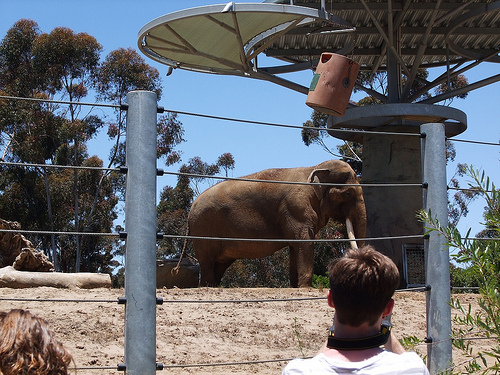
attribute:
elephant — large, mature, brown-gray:
[170, 159, 366, 287]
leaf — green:
[92, 135, 97, 140]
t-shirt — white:
[280, 345, 430, 373]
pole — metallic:
[123, 90, 157, 374]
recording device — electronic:
[377, 305, 391, 330]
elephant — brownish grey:
[160, 149, 362, 293]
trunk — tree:
[31, 229, 133, 328]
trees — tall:
[1, 12, 128, 289]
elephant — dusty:
[216, 161, 431, 282]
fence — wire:
[4, 85, 498, 372]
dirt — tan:
[175, 291, 253, 363]